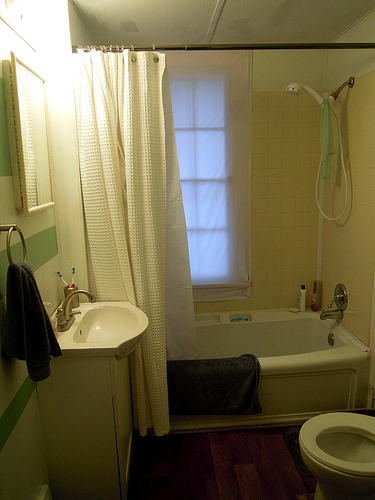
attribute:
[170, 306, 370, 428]
bathtub — white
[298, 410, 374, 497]
toilet — white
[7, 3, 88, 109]
light — shining, bright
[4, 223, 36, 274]
rack — towel rack, round, silver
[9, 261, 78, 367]
towel — black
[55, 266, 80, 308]
toothbrushes can — silver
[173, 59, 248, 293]
curtains — drawn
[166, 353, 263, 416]
bath towel — black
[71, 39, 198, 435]
shower curtain — white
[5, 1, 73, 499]
wall — painted, green, striped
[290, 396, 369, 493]
toilet — white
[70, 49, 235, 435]
curtain — shower curtain, long, white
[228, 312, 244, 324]
handle — blue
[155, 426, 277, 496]
floors — hardwood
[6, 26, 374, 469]
scene — inside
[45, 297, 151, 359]
sink — white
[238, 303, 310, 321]
area — outer